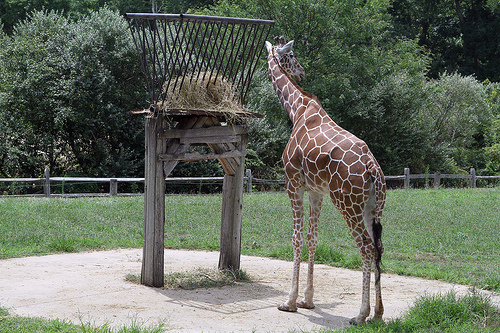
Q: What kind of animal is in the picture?
A: A giraffe.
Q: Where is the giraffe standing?
A: At a feeding place.